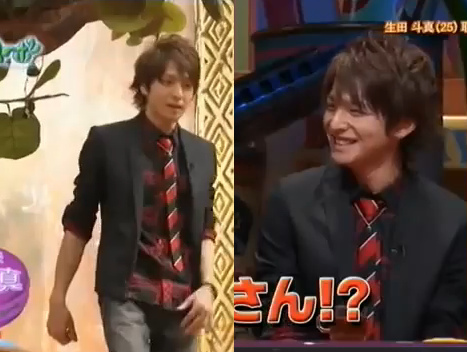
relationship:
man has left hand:
[263, 35, 456, 335] [37, 290, 89, 340]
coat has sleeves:
[72, 103, 222, 308] [55, 129, 115, 245]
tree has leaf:
[9, 2, 47, 158] [0, 96, 43, 161]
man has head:
[263, 35, 456, 335] [310, 41, 427, 170]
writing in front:
[216, 256, 379, 332] [4, 207, 465, 333]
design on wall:
[11, 10, 60, 153] [2, 2, 231, 349]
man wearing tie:
[263, 35, 456, 335] [152, 130, 207, 272]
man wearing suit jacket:
[263, 35, 456, 335] [72, 103, 222, 308]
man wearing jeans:
[263, 35, 456, 335] [99, 276, 194, 350]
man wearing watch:
[263, 35, 456, 335] [195, 270, 219, 296]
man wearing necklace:
[263, 35, 456, 335] [341, 191, 398, 230]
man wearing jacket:
[263, 35, 456, 335] [72, 103, 222, 308]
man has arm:
[79, 35, 226, 349] [52, 216, 95, 344]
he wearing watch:
[79, 35, 226, 349] [195, 270, 219, 296]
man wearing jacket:
[79, 35, 226, 349] [72, 103, 222, 308]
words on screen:
[232, 271, 370, 324] [2, 3, 462, 347]